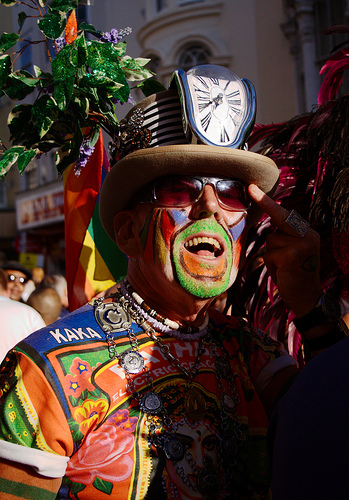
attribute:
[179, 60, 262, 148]
clock — blue, framed, white, analog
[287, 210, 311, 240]
ring — silver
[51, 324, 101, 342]
letters — white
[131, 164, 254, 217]
glasses — brown